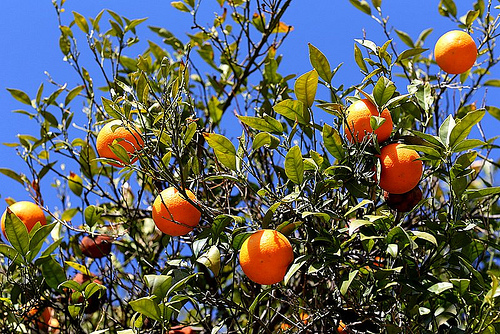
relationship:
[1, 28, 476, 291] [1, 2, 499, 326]
oranges on tree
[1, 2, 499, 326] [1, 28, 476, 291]
tree has oranges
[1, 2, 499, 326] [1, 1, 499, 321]
tree has leaves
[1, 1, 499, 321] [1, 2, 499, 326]
leaves are on tree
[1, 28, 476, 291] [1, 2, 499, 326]
oranges are  in tree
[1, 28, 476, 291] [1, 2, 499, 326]
oranges are on tree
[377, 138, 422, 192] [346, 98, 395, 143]
orange next to orange